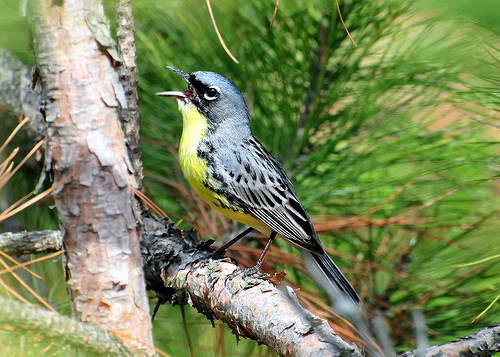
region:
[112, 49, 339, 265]
bird on the branch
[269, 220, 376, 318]
tail feather of the bird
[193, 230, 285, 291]
feet of the bird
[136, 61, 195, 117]
beak of the bird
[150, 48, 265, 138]
head of the bird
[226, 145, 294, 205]
feathers on the bird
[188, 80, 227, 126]
eye of the bird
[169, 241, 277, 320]
branch under the bird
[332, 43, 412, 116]
tree in the background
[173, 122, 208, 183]
yellow chest of the bird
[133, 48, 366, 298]
the bird on the branch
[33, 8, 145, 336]
the tree trunk beside the bird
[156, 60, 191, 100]
the beak of the bird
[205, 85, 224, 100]
the eye of the bird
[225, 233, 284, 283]
the leg of the bird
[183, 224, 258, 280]
the leg of the bird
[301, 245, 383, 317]
the tail of the bird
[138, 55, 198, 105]
the beak of the bird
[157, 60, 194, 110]
the beak is open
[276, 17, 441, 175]
palm fronds behind the bird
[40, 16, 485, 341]
bird standing on rough branch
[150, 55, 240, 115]
open beak showing pink mouth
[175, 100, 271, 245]
yellow feathers on underside of bird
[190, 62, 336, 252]
blue feathers with black markings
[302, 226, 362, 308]
long tail feathers in black and white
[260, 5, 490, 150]
evergreen branch with long needle leaves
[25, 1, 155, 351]
white bark peeling off orange trunk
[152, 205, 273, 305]
thin black legs slanted across branch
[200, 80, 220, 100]
round and black eye with white semicircles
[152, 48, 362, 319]
bird standing in profile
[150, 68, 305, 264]
yellow and gray bird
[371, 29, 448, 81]
tall green and yellow grass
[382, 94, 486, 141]
tall green and yellow grass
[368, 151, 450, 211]
tall green and yellow grass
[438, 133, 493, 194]
tall green and yellow grass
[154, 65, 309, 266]
bird on branch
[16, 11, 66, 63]
tall green and yellow grass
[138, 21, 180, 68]
tall green and yellow grass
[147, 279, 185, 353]
tall green and yellow grass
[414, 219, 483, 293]
tall green and yellow grass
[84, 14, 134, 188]
peeling bark on tree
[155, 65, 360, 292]
bird standing on branch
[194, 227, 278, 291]
bird legs on branch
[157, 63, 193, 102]
open beak of bird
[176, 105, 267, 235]
yellow chest of bird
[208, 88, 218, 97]
black eye with reflection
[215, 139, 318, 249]
black and white wing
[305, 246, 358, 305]
tail feathers of bird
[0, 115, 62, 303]
dried brown tree needles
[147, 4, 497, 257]
branch with green needles